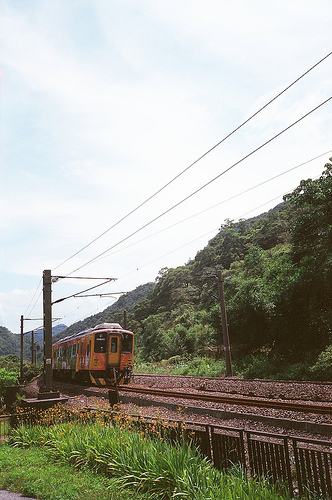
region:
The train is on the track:
[22, 322, 164, 402]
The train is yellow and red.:
[50, 328, 138, 379]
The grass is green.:
[62, 409, 192, 499]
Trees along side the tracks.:
[144, 280, 319, 356]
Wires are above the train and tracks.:
[62, 238, 183, 284]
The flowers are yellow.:
[51, 402, 179, 439]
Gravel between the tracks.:
[179, 379, 317, 408]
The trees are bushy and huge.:
[161, 258, 328, 362]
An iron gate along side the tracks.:
[184, 421, 317, 486]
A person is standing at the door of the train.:
[107, 335, 125, 368]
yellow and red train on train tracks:
[44, 316, 157, 389]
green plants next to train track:
[43, 388, 187, 497]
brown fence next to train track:
[193, 415, 311, 488]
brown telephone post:
[208, 266, 242, 385]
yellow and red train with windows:
[50, 322, 146, 393]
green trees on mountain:
[147, 252, 236, 360]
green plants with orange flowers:
[128, 408, 225, 480]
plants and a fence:
[123, 407, 207, 473]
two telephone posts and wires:
[16, 260, 67, 409]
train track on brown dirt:
[147, 371, 229, 432]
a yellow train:
[24, 310, 235, 416]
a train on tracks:
[50, 316, 200, 419]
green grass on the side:
[77, 427, 119, 473]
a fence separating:
[205, 416, 271, 468]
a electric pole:
[39, 265, 82, 409]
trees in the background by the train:
[189, 244, 325, 311]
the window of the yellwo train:
[107, 336, 138, 354]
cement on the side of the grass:
[11, 489, 29, 498]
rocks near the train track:
[197, 379, 238, 390]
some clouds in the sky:
[15, 200, 96, 235]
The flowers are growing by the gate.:
[57, 401, 170, 423]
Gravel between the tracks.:
[172, 378, 271, 400]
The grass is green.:
[63, 432, 160, 482]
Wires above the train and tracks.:
[39, 261, 124, 322]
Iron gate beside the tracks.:
[208, 429, 300, 472]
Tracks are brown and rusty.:
[201, 369, 331, 433]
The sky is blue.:
[49, 164, 244, 237]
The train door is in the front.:
[107, 336, 133, 370]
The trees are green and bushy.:
[184, 244, 328, 345]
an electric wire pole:
[38, 267, 74, 299]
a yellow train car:
[58, 320, 138, 378]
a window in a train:
[95, 336, 107, 355]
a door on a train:
[102, 328, 126, 368]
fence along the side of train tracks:
[266, 421, 325, 471]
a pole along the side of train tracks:
[213, 266, 234, 376]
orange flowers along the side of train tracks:
[55, 391, 104, 460]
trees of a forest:
[161, 282, 201, 334]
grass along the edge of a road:
[8, 480, 29, 497]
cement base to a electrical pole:
[25, 391, 72, 408]